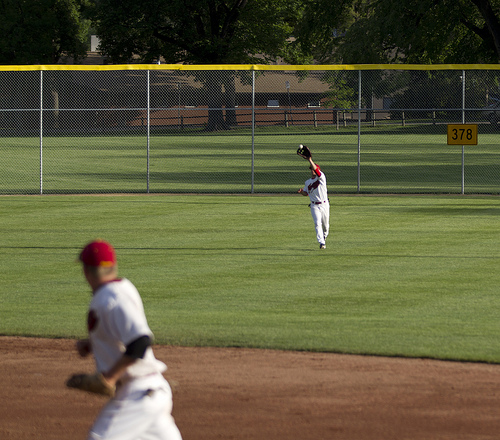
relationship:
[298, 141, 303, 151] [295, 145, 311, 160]
ball inside glove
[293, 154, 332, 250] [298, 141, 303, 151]
man catching ball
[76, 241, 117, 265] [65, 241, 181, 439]
cap on player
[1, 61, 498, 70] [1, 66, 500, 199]
yellow lining chain link fence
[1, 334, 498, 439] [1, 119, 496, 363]
dirt in grass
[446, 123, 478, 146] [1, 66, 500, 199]
number sign attached to chain link fence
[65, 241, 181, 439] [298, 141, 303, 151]
player throwing ball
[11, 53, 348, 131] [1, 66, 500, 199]
building outside chain link fence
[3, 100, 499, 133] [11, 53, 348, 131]
fence surrounding building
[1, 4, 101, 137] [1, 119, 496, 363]
tree by grass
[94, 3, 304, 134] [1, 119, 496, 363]
tree by grass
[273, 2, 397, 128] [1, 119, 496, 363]
tree by grass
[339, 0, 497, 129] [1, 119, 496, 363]
tree by grass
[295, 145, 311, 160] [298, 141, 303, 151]
glove has ball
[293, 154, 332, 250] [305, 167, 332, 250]
man has uniform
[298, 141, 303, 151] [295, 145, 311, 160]
ball heading for glove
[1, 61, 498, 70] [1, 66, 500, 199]
yellow at top of chain link fence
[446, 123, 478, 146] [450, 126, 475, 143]
number sign has numbers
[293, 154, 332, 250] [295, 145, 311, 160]
man wearing glove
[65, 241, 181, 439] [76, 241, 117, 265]
player wearing cap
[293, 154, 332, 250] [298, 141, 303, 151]
man catching fly ball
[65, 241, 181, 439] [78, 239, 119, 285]
player turning head